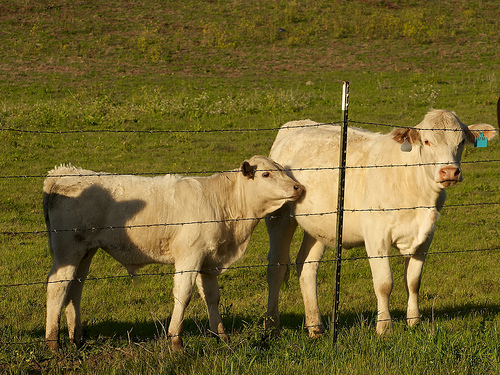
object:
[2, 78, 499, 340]
fence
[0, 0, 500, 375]
ground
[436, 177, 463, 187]
mouth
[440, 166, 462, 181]
nose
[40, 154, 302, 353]
cow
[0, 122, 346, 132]
wire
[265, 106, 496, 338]
cow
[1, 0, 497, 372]
field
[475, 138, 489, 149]
tag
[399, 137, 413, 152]
tag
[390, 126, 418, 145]
ear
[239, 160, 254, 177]
ear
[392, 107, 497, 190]
head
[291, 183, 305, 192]
nose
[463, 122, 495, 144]
ear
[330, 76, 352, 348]
post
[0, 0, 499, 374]
grass